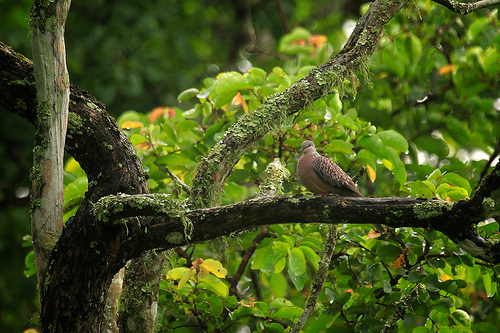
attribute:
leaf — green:
[268, 302, 305, 320]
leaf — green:
[377, 128, 409, 155]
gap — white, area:
[416, 134, 483, 159]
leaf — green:
[163, 262, 190, 283]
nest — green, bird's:
[103, 192, 181, 216]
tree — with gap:
[36, 62, 453, 269]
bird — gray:
[251, 109, 428, 238]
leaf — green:
[184, 255, 226, 283]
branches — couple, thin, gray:
[218, 227, 499, 329]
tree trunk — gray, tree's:
[28, 0, 73, 315]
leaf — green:
[370, 137, 408, 187]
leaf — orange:
[311, 31, 356, 59]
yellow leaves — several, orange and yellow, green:
[128, 129, 173, 155]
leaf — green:
[287, 238, 305, 277]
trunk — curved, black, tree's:
[58, 95, 146, 200]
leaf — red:
[145, 107, 178, 121]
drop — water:
[308, 91, 339, 129]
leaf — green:
[359, 131, 392, 162]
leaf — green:
[288, 247, 308, 276]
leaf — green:
[341, 95, 430, 187]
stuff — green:
[90, 190, 194, 229]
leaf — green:
[383, 149, 410, 189]